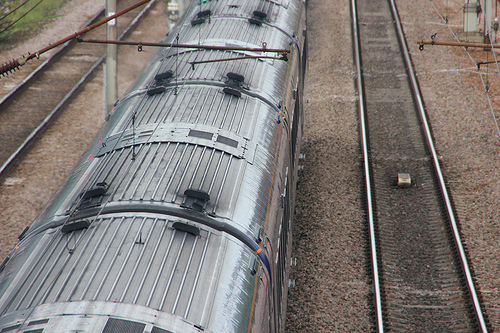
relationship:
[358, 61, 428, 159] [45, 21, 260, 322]
tracks for train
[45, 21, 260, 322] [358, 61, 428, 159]
train on tracks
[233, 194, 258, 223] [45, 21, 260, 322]
sunlight reflecting on train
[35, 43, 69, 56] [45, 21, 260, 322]
power line above train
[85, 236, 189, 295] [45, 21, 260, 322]
roof of train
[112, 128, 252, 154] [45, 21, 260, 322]
plate on train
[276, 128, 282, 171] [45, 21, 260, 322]
stripe on train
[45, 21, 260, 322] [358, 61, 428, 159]
train next to tracks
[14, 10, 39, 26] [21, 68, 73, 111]
grass next to tracks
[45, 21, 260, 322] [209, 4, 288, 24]
train has car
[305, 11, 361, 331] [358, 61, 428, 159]
gravel on tracks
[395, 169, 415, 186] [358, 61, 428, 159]
box on tracks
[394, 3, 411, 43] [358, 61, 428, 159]
rail on tracks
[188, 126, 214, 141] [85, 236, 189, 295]
vent on roof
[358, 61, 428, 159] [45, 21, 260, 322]
tracks next to train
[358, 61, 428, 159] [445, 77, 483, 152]
tracks on ground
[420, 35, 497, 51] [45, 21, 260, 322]
pole next to train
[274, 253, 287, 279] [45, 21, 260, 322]
window on train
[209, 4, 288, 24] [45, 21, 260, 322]
car on train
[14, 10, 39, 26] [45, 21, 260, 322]
grass next to train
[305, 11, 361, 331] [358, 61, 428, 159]
gravel by tracks